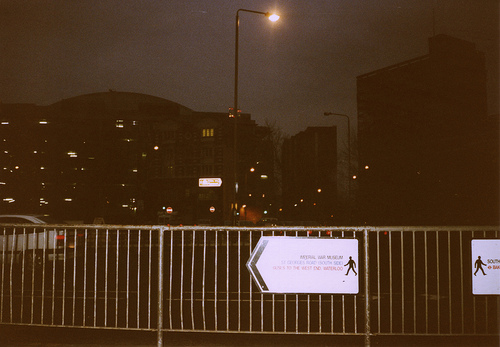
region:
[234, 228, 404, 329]
the sign is white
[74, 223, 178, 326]
the railing is made of metal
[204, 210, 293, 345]
the railing is made of metal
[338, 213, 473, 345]
the railing is made of metal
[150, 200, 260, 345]
the railing is made of metal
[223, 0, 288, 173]
a thin grey street light.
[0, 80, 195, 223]
a bunch of buildings with lights on.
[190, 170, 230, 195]
a red and white sign.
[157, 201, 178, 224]
a red and white stop sign.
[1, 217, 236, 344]
a long thin grey fence.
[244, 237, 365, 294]
a black and white direction sign.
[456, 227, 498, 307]
a black and white sign says south.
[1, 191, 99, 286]
a white vehicle is parked.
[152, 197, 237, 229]
two street signs says stop.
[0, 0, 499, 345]
a dark picture of a bunch of buildings.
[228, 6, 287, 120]
street light of the place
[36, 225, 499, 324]
steel fencing with some advertisement board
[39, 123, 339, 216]
street lights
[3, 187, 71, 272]
white color car parked in the parking area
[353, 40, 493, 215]
a big building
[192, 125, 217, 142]
window of the building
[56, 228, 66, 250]
danger light of the car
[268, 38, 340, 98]
a sky with clouds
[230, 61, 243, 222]
post of the street light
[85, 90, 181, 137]
mountain near the buildings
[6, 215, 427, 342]
A metal fence with a sign on it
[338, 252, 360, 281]
An image of a person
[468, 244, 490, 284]
An image of a person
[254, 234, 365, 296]
A sign with an image of a person on it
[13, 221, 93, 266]
White car on the street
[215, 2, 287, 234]
A street light lit up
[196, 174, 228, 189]
A sign lit up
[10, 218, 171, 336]
This fence is made of iron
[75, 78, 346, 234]
A city at night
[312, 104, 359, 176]
A street light not lit up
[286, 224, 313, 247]
edge of a board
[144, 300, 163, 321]
apart of a metal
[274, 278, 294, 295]
edge of a board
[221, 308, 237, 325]
part of a fence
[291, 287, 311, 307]
edge of a board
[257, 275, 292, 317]
part of a board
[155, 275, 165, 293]
part of a metal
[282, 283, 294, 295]
edge of a board